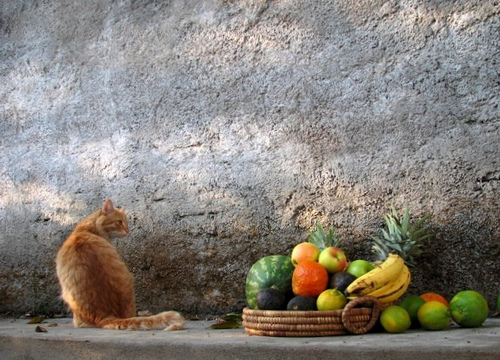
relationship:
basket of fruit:
[239, 298, 382, 338] [244, 203, 433, 309]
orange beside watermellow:
[291, 256, 331, 298] [243, 253, 294, 310]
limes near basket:
[381, 288, 490, 334] [239, 298, 382, 338]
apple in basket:
[319, 246, 348, 273] [239, 298, 382, 338]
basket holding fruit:
[239, 298, 382, 338] [244, 203, 433, 309]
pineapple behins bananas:
[367, 203, 437, 273] [347, 251, 412, 305]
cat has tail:
[53, 198, 185, 334] [103, 309, 188, 333]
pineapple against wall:
[367, 203, 437, 273] [2, 1, 500, 317]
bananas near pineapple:
[347, 251, 412, 305] [367, 203, 437, 273]